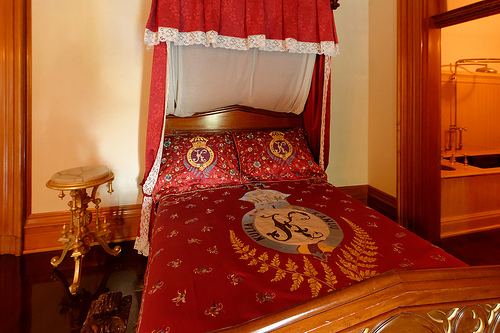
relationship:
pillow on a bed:
[156, 130, 245, 196] [135, 101, 496, 332]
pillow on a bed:
[230, 118, 329, 183] [135, 101, 496, 332]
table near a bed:
[42, 162, 126, 300] [135, 101, 496, 332]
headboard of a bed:
[157, 99, 307, 137] [135, 101, 496, 332]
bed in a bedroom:
[135, 101, 496, 332] [2, 1, 500, 321]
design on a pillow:
[179, 135, 219, 180] [156, 130, 245, 196]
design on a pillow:
[263, 129, 299, 171] [230, 118, 329, 183]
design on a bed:
[220, 185, 384, 299] [135, 101, 496, 332]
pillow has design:
[156, 130, 245, 196] [179, 135, 219, 180]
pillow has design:
[230, 118, 329, 183] [263, 129, 299, 171]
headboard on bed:
[157, 99, 307, 137] [135, 101, 496, 332]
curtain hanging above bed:
[134, 0, 340, 260] [135, 101, 496, 332]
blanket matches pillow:
[135, 178, 466, 332] [156, 130, 245, 196]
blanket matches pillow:
[135, 178, 466, 332] [230, 118, 329, 183]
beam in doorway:
[425, 1, 500, 33] [414, 2, 500, 274]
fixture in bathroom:
[445, 111, 467, 149] [430, 1, 498, 225]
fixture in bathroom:
[446, 148, 471, 170] [430, 1, 498, 225]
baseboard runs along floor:
[19, 199, 145, 255] [0, 242, 157, 331]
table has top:
[42, 162, 126, 300] [46, 162, 113, 187]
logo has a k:
[220, 185, 384, 299] [263, 209, 320, 251]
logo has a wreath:
[220, 185, 384, 299] [218, 212, 381, 301]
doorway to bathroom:
[414, 2, 500, 274] [430, 1, 498, 225]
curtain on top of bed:
[134, 0, 340, 260] [135, 101, 496, 332]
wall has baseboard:
[29, 2, 402, 213] [19, 199, 145, 255]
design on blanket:
[220, 185, 384, 299] [135, 178, 466, 332]